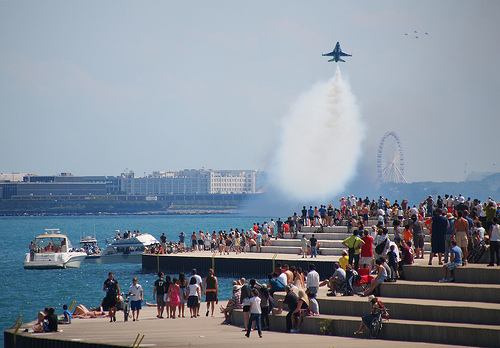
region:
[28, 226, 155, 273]
3 fishing boats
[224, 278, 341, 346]
people sitting on stairs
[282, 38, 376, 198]
jet with trails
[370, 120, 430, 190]
a ferris wheel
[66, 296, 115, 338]
ladies sunbathing on concrete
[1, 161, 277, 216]
bunch of hotels on boardwalk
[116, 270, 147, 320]
a man with a bicycle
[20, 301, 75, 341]
people sitting on sidewalk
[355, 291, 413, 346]
lady with a bicycle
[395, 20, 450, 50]
4 small planes in sky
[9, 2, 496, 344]
an air show on the thames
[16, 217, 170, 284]
boats anchored in the river thames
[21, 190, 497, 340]
crowds of spectators watching the jets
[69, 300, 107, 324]
a girl is sunbathing in the park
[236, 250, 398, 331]
people are sitting on the steps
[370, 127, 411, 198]
the london eye in the distance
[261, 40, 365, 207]
smoke trail from the jet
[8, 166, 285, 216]
buildings along the water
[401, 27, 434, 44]
four jets are coming towards the crowd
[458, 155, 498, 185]
towers are on the horizon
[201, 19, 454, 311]
people watching airplanes do tricks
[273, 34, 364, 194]
jet trails white smoke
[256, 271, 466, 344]
people sitting on large cement stairs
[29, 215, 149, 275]
boats are nearby in the water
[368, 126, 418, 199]
large Ferris wheel is in the background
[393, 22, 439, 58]
four jets are in the far distance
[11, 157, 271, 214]
large buildings in the distance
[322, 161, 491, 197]
green hills in the distant background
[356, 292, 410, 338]
woman sitting on bleacher style cement stairs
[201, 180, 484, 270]
most spectators are not facing the camera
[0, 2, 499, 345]
large group of people watching an airshow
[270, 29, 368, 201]
jet plane leaving a trail of smoke behind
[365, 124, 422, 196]
Ferris wheel in the distance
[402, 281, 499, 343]
large cement steps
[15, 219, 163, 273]
boats in the water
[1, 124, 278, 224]
large buildings in the distance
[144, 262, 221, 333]
group of people walking away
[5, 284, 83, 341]
people sitting by the water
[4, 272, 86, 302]
blue water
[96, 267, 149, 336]
people walking closer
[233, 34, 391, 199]
jet shooting up into the air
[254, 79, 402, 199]
white billowing cloud of jet stream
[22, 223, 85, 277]
ferry on the lake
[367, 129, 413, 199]
ferris wheel in the background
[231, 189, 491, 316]
large crowd watching a jet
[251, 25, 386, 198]
jet flying up into space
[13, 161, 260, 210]
buildings on the coast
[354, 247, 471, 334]
cement steps with people sitting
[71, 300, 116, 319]
woman in a bikini sunbathing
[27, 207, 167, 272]
people watching a jet from the boat